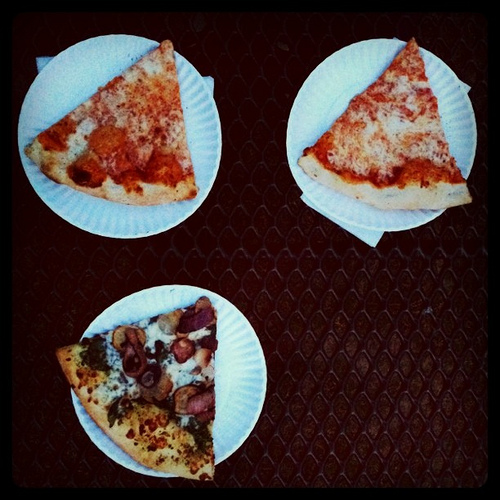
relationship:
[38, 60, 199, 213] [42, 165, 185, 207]
pizza has crust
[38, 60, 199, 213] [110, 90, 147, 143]
pizza has cheese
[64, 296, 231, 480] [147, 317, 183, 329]
pizza has onion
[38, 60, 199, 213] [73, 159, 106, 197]
pizza has burn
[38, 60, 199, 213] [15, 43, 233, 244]
pizza on plate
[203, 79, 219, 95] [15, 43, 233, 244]
napkin under plate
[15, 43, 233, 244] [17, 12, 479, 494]
plate on table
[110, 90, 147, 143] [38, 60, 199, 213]
cheese on pizza